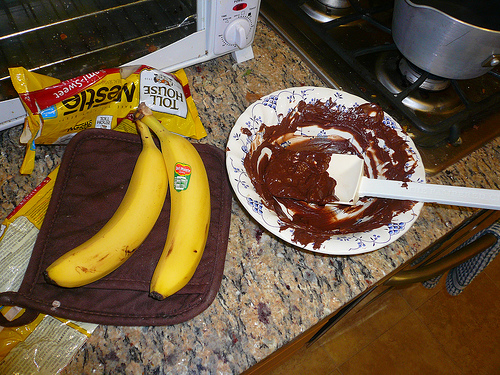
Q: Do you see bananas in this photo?
A: Yes, there is a banana.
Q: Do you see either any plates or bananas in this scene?
A: Yes, there is a banana.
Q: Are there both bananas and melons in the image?
A: No, there is a banana but no melons.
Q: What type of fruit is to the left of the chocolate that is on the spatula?
A: The fruit is a banana.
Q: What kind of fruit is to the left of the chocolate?
A: The fruit is a banana.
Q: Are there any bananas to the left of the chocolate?
A: Yes, there is a banana to the left of the chocolate.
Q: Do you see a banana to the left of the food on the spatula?
A: Yes, there is a banana to the left of the chocolate.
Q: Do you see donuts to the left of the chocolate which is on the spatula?
A: No, there is a banana to the left of the chocolate.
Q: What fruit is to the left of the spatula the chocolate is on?
A: The fruit is a banana.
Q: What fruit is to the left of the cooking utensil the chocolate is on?
A: The fruit is a banana.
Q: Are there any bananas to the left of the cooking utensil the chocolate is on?
A: Yes, there is a banana to the left of the spatula.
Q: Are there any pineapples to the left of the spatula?
A: No, there is a banana to the left of the spatula.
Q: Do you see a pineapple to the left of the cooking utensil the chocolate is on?
A: No, there is a banana to the left of the spatula.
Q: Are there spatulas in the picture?
A: Yes, there is a spatula.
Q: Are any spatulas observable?
A: Yes, there is a spatula.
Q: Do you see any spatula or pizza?
A: Yes, there is a spatula.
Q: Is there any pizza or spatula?
A: Yes, there is a spatula.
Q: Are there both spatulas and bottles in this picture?
A: No, there is a spatula but no bottles.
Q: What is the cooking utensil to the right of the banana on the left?
A: The cooking utensil is a spatula.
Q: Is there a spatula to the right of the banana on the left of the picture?
A: Yes, there is a spatula to the right of the banana.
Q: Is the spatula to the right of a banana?
A: Yes, the spatula is to the right of a banana.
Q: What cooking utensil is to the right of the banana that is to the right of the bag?
A: The cooking utensil is a spatula.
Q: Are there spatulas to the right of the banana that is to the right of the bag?
A: Yes, there is a spatula to the right of the banana.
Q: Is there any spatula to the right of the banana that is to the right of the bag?
A: Yes, there is a spatula to the right of the banana.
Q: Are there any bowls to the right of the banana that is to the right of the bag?
A: No, there is a spatula to the right of the banana.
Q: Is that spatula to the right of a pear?
A: No, the spatula is to the right of a banana.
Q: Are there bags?
A: Yes, there is a bag.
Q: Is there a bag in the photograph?
A: Yes, there is a bag.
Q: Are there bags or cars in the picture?
A: Yes, there is a bag.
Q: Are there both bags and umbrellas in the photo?
A: No, there is a bag but no umbrellas.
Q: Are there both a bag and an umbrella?
A: No, there is a bag but no umbrellas.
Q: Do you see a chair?
A: No, there are no chairs.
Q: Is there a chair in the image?
A: No, there are no chairs.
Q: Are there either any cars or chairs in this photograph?
A: No, there are no chairs or cars.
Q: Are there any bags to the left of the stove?
A: Yes, there is a bag to the left of the stove.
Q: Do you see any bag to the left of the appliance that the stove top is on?
A: Yes, there is a bag to the left of the stove.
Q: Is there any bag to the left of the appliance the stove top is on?
A: Yes, there is a bag to the left of the stove.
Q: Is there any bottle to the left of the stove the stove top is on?
A: No, there is a bag to the left of the stove.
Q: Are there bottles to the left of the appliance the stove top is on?
A: No, there is a bag to the left of the stove.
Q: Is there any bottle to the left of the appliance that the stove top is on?
A: No, there is a bag to the left of the stove.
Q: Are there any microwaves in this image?
A: Yes, there is a microwave.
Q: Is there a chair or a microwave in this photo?
A: Yes, there is a microwave.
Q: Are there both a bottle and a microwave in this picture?
A: No, there is a microwave but no bottles.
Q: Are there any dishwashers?
A: No, there are no dishwashers.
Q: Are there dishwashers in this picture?
A: No, there are no dishwashers.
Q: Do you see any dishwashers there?
A: No, there are no dishwashers.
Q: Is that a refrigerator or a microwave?
A: That is a microwave.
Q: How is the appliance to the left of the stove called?
A: The appliance is a microwave.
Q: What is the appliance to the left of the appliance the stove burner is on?
A: The appliance is a microwave.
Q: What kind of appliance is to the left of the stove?
A: The appliance is a microwave.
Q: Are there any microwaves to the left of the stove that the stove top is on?
A: Yes, there is a microwave to the left of the stove.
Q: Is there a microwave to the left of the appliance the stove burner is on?
A: Yes, there is a microwave to the left of the stove.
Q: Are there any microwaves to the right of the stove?
A: No, the microwave is to the left of the stove.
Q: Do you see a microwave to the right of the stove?
A: No, the microwave is to the left of the stove.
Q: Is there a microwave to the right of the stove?
A: No, the microwave is to the left of the stove.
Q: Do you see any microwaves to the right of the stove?
A: No, the microwave is to the left of the stove.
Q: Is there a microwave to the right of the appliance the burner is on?
A: No, the microwave is to the left of the stove.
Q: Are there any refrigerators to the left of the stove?
A: No, there is a microwave to the left of the stove.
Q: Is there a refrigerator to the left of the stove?
A: No, there is a microwave to the left of the stove.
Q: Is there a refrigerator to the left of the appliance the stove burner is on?
A: No, there is a microwave to the left of the stove.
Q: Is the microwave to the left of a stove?
A: Yes, the microwave is to the left of a stove.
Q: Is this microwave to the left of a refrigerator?
A: No, the microwave is to the left of a stove.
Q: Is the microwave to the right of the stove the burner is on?
A: No, the microwave is to the left of the stove.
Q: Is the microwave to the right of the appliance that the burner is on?
A: No, the microwave is to the left of the stove.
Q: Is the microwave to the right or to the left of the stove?
A: The microwave is to the left of the stove.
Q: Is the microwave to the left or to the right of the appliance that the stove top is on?
A: The microwave is to the left of the stove.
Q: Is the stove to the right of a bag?
A: Yes, the stove is to the right of a bag.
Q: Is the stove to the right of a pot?
A: No, the stove is to the right of a bag.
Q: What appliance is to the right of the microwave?
A: The appliance is a stove.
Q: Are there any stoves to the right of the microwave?
A: Yes, there is a stove to the right of the microwave.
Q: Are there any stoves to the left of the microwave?
A: No, the stove is to the right of the microwave.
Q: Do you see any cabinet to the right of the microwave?
A: No, there is a stove to the right of the microwave.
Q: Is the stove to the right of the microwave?
A: Yes, the stove is to the right of the microwave.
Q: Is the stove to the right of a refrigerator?
A: No, the stove is to the right of the microwave.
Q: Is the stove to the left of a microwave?
A: No, the stove is to the right of a microwave.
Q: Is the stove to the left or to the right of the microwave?
A: The stove is to the right of the microwave.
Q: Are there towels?
A: Yes, there is a towel.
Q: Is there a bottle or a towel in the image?
A: Yes, there is a towel.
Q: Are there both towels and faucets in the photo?
A: No, there is a towel but no faucets.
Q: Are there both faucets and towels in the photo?
A: No, there is a towel but no faucets.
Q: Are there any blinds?
A: No, there are no blinds.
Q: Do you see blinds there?
A: No, there are no blinds.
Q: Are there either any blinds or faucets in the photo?
A: No, there are no blinds or faucets.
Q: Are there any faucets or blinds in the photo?
A: No, there are no blinds or faucets.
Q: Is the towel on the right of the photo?
A: Yes, the towel is on the right of the image.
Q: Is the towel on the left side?
A: No, the towel is on the right of the image.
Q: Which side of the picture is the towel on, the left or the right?
A: The towel is on the right of the image.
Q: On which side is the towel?
A: The towel is on the right of the image.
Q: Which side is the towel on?
A: The towel is on the right of the image.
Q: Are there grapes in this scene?
A: No, there are no grapes.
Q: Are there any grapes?
A: No, there are no grapes.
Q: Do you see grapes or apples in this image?
A: No, there are no grapes or apples.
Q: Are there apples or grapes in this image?
A: No, there are no grapes or apples.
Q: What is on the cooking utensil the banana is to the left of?
A: The chocolate is on the spatula.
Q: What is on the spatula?
A: The chocolate is on the spatula.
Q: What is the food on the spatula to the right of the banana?
A: The food is chocolate.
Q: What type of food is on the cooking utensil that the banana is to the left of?
A: The food is chocolate.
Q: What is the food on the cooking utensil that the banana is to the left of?
A: The food is chocolate.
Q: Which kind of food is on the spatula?
A: The food is chocolate.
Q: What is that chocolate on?
A: The chocolate is on the spatula.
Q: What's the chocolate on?
A: The chocolate is on the spatula.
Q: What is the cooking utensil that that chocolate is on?
A: The cooking utensil is a spatula.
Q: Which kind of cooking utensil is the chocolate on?
A: The chocolate is on the spatula.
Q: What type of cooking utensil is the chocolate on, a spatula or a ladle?
A: The chocolate is on a spatula.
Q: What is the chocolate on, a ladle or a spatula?
A: The chocolate is on a spatula.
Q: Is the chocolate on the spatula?
A: Yes, the chocolate is on the spatula.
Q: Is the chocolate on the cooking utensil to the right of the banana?
A: Yes, the chocolate is on the spatula.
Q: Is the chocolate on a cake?
A: No, the chocolate is on the spatula.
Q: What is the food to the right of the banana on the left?
A: The food is chocolate.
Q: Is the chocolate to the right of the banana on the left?
A: Yes, the chocolate is to the right of the banana.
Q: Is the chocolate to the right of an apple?
A: No, the chocolate is to the right of the banana.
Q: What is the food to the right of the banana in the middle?
A: The food is chocolate.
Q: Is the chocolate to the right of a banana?
A: Yes, the chocolate is to the right of a banana.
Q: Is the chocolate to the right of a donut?
A: No, the chocolate is to the right of a banana.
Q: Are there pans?
A: Yes, there is a pan.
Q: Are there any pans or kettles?
A: Yes, there is a pan.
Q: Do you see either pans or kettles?
A: Yes, there is a pan.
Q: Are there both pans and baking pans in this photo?
A: No, there is a pan but no baking pans.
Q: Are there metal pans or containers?
A: Yes, there is a metal pan.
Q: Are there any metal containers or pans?
A: Yes, there is a metal pan.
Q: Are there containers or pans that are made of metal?
A: Yes, the pan is made of metal.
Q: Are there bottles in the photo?
A: No, there are no bottles.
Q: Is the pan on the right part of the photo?
A: Yes, the pan is on the right of the image.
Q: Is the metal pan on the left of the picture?
A: No, the pan is on the right of the image.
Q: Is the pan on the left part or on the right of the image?
A: The pan is on the right of the image.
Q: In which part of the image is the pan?
A: The pan is on the right of the image.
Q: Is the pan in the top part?
A: Yes, the pan is in the top of the image.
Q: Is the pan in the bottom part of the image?
A: No, the pan is in the top of the image.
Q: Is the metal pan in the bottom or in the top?
A: The pan is in the top of the image.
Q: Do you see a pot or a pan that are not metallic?
A: No, there is a pan but it is metallic.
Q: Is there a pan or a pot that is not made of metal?
A: No, there is a pan but it is made of metal.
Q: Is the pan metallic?
A: Yes, the pan is metallic.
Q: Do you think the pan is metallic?
A: Yes, the pan is metallic.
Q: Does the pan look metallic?
A: Yes, the pan is metallic.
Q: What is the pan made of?
A: The pan is made of metal.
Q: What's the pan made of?
A: The pan is made of metal.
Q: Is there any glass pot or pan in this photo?
A: No, there is a pan but it is metallic.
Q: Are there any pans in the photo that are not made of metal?
A: No, there is a pan but it is made of metal.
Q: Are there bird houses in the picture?
A: No, there are no bird houses.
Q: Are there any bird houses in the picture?
A: No, there are no bird houses.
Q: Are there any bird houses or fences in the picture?
A: No, there are no bird houses or fences.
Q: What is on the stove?
A: The stove burner is on the stove.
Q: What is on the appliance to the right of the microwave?
A: The stove burner is on the stove.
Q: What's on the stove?
A: The stove burner is on the stove.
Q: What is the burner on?
A: The burner is on the stove.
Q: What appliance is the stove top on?
A: The stove top is on the stove.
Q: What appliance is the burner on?
A: The stove top is on the stove.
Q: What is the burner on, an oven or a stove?
A: The burner is on a stove.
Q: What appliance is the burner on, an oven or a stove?
A: The burner is on a stove.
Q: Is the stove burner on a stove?
A: Yes, the stove burner is on a stove.